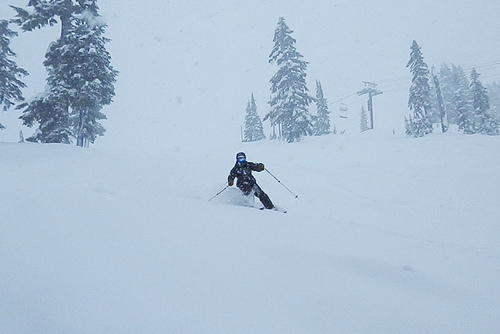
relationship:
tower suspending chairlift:
[358, 86, 381, 98] [340, 107, 349, 120]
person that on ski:
[227, 152, 276, 210] [249, 201, 265, 210]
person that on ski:
[227, 152, 276, 210] [274, 206, 290, 215]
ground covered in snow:
[0, 129, 499, 334] [6, 211, 493, 325]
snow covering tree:
[285, 57, 300, 68] [262, 15, 319, 142]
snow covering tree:
[285, 57, 300, 68] [248, 86, 264, 139]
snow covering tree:
[285, 57, 300, 68] [244, 99, 252, 140]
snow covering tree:
[285, 57, 300, 68] [314, 78, 331, 134]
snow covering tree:
[285, 57, 300, 68] [359, 105, 369, 132]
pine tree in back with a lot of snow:
[241, 92, 268, 143] [341, 149, 451, 274]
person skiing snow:
[209, 148, 308, 222] [9, 134, 492, 310]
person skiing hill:
[227, 152, 276, 210] [86, 137, 200, 280]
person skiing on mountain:
[227, 152, 276, 210] [43, 99, 480, 301]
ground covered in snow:
[29, 129, 476, 314] [3, 215, 499, 332]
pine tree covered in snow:
[241, 92, 268, 143] [0, 2, 499, 332]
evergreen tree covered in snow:
[263, 14, 319, 143] [0, 2, 499, 332]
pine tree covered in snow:
[308, 78, 333, 136] [0, 2, 499, 332]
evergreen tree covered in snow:
[399, 35, 442, 136] [0, 2, 499, 332]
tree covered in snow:
[431, 64, 449, 129] [0, 2, 499, 332]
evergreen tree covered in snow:
[263, 14, 319, 143] [269, 19, 311, 139]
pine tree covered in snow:
[241, 92, 268, 143] [241, 110, 261, 140]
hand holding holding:
[254, 160, 268, 172] [261, 165, 298, 198]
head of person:
[230, 147, 249, 166] [228, 152, 278, 212]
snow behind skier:
[188, 176, 242, 225] [216, 141, 293, 221]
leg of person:
[253, 182, 273, 207] [225, 151, 276, 208]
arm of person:
[248, 155, 263, 172] [227, 152, 276, 210]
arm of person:
[226, 168, 238, 194] [231, 155, 277, 215]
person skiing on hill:
[227, 152, 276, 210] [0, 130, 499, 334]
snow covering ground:
[156, 165, 413, 297] [0, 129, 499, 334]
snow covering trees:
[267, 10, 497, 130] [234, 16, 498, 146]